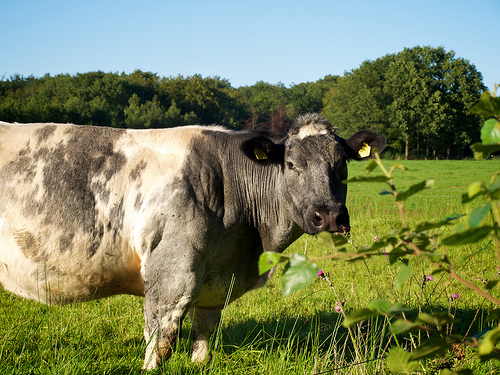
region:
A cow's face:
[226, 88, 388, 281]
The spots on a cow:
[7, 118, 205, 278]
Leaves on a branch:
[373, 148, 488, 373]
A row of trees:
[30, 63, 498, 121]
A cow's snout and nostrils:
[286, 170, 351, 250]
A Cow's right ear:
[240, 120, 290, 181]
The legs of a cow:
[37, 247, 257, 368]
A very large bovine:
[6, 123, 356, 343]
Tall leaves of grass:
[8, 312, 93, 372]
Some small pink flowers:
[310, 255, 485, 322]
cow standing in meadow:
[55, 100, 400, 360]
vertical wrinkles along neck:
[220, 115, 296, 235]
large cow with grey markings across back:
[10, 105, 385, 350]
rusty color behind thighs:
[90, 240, 165, 300]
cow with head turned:
[247, 105, 377, 260]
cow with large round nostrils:
[240, 110, 400, 252]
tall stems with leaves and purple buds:
[265, 160, 475, 355]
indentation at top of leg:
[140, 200, 172, 260]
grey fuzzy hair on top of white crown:
[286, 100, 338, 152]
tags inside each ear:
[216, 120, 391, 316]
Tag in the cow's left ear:
[358, 141, 375, 158]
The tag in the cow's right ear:
[254, 148, 267, 160]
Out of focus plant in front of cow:
[253, 114, 499, 373]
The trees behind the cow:
[0, 39, 492, 162]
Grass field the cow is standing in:
[2, 158, 495, 373]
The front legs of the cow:
[128, 212, 223, 372]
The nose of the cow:
[306, 202, 351, 238]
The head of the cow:
[280, 116, 352, 241]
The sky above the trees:
[0, 0, 497, 96]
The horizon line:
[0, 48, 497, 101]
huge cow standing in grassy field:
[1, 116, 361, 359]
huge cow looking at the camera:
[0, 117, 385, 355]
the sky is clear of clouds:
[1, 0, 498, 79]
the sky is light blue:
[0, 0, 499, 100]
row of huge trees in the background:
[0, 56, 497, 159]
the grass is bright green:
[0, 157, 497, 374]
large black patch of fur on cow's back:
[0, 121, 152, 261]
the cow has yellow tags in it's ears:
[0, 99, 383, 371]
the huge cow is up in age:
[0, 114, 387, 370]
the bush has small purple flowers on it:
[251, 88, 498, 373]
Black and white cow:
[4, 105, 397, 361]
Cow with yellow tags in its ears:
[241, 102, 388, 249]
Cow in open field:
[16, 42, 488, 347]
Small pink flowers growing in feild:
[300, 253, 492, 364]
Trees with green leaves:
[350, 45, 499, 153]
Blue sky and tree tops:
[12, 7, 492, 119]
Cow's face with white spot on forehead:
[282, 115, 354, 234]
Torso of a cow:
[2, 117, 237, 329]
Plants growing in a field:
[348, 183, 490, 370]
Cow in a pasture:
[57, 127, 487, 314]